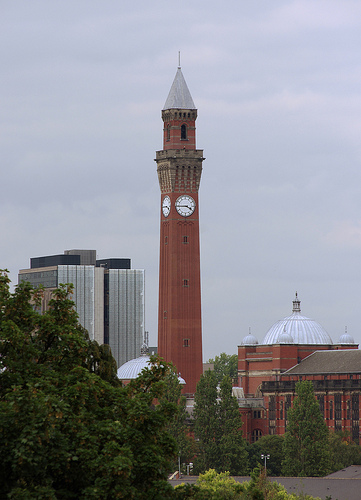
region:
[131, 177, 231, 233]
a clock on a building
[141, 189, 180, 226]
a large clock on abuilindg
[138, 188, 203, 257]
an outside clock on a building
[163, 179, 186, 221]
a large outside clock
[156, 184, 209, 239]
a large outside clock on building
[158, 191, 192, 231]
a building with clock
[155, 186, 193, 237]
a building with large clock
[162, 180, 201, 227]
a building with outside clcok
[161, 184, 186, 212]
a building with large outside clock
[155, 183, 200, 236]
a clock on a tall building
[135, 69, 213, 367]
large red brick tower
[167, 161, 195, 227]
white clock on tower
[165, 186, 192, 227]
black hands on clock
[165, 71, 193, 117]
grey top of tower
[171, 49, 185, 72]
pole on top of tower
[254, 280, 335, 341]
white dome near tower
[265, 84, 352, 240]
sky is grey and cloudy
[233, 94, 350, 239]
grey and thick clouds in sky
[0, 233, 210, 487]
green trees in front of tower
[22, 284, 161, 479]
green and leafy trees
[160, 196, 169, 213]
a large black and white clock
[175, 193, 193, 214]
a large black and white clock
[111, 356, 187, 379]
a silver white dome on the building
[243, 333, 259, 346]
a silver white dome on the building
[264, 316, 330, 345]
a silver white dome on the building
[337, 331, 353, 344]
a silver white dome on the building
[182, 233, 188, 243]
a small window on the tower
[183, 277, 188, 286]
a small window on the tower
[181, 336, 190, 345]
a small window on the tower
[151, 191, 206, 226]
a clock on a building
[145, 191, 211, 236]
a large clock on a building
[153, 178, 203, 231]
an outside clock on a building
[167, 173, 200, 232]
a large outside clock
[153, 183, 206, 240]
an outside large clock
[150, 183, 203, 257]
a large outside clock on a building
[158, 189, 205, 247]
an outside large clock on a building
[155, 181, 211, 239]
a building with large clock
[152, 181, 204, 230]
a building with an outside clock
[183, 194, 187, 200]
roman numeral on clock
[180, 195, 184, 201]
long black colored sock